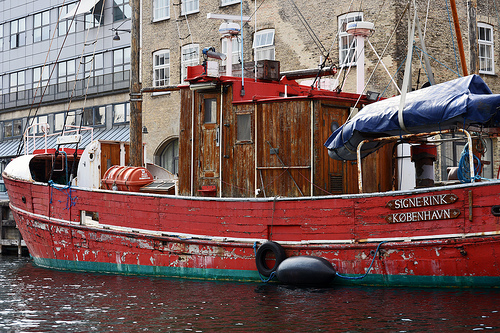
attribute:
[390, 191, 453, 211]
writing — white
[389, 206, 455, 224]
lettering — white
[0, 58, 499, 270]
boat — wooden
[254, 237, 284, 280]
wheel — black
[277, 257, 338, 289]
float — black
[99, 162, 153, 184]
barrel — orange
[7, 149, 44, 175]
front — white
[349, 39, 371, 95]
pole — white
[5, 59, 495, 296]
boat — old, wooden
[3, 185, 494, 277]
boat paint — worn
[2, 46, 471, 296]
boat — in the water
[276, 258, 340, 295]
black object — against the boat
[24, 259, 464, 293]
green wood — at bottom of the boat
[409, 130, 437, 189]
person — driving the boat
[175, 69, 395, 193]
wooden cabin — brown, on the boat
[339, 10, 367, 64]
window — to the right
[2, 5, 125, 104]
building — large, gray, with many windows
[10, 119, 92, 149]
white railing — on the boat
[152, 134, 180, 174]
curved doorway — on a building